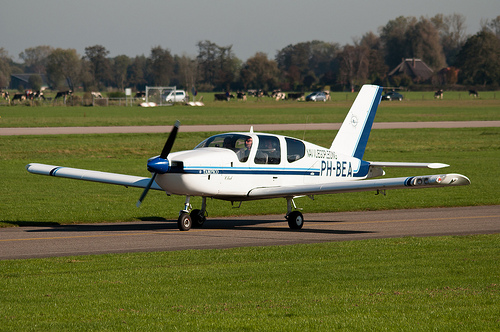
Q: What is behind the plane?
A: There are cows behind the plane.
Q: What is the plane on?
A: A concrete road.